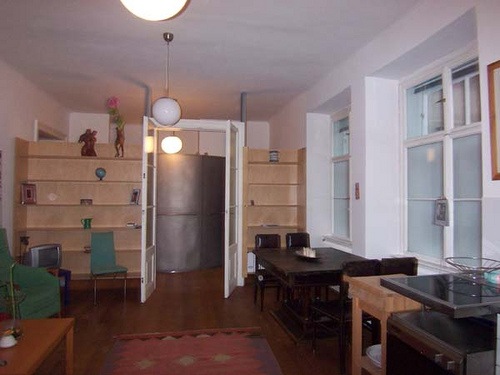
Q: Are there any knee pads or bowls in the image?
A: No, there are no bowls or knee pads.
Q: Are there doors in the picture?
A: Yes, there is a door.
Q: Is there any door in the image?
A: Yes, there is a door.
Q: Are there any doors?
A: Yes, there is a door.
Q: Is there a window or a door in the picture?
A: Yes, there is a door.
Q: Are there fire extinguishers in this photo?
A: No, there are no fire extinguishers.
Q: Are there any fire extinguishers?
A: No, there are no fire extinguishers.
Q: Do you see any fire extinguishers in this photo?
A: No, there are no fire extinguishers.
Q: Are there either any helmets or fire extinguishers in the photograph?
A: No, there are no fire extinguishers or helmets.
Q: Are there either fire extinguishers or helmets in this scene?
A: No, there are no fire extinguishers or helmets.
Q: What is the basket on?
A: The basket is on the counter.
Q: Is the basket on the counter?
A: Yes, the basket is on the counter.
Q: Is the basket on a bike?
A: No, the basket is on the counter.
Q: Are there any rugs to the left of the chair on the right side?
A: Yes, there is a rug to the left of the chair.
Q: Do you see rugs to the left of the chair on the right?
A: Yes, there is a rug to the left of the chair.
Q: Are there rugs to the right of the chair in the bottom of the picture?
A: No, the rug is to the left of the chair.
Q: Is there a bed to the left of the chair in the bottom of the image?
A: No, there is a rug to the left of the chair.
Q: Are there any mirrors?
A: No, there are no mirrors.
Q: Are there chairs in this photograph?
A: Yes, there is a chair.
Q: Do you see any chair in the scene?
A: Yes, there is a chair.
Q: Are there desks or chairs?
A: Yes, there is a chair.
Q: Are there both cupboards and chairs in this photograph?
A: No, there is a chair but no cupboards.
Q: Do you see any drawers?
A: No, there are no drawers.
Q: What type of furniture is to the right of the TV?
A: The piece of furniture is a chair.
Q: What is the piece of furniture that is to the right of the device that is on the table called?
A: The piece of furniture is a chair.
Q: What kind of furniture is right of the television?
A: The piece of furniture is a chair.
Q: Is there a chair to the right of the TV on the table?
A: Yes, there is a chair to the right of the TV.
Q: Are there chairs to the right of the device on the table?
A: Yes, there is a chair to the right of the TV.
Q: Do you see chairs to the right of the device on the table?
A: Yes, there is a chair to the right of the TV.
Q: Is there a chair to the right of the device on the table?
A: Yes, there is a chair to the right of the TV.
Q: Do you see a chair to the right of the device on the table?
A: Yes, there is a chair to the right of the TV.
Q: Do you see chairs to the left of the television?
A: No, the chair is to the right of the television.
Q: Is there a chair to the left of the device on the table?
A: No, the chair is to the right of the television.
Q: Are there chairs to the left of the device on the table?
A: No, the chair is to the right of the television.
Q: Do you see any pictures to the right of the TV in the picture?
A: No, there is a chair to the right of the TV.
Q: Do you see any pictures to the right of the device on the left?
A: No, there is a chair to the right of the TV.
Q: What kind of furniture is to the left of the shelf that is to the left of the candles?
A: The piece of furniture is a chair.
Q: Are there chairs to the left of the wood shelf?
A: Yes, there is a chair to the left of the shelf.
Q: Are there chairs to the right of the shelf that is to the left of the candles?
A: No, the chair is to the left of the shelf.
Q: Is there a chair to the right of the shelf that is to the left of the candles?
A: No, the chair is to the left of the shelf.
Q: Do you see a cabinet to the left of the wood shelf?
A: No, there is a chair to the left of the shelf.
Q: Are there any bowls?
A: No, there are no bowls.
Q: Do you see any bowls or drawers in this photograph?
A: No, there are no bowls or drawers.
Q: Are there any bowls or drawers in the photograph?
A: No, there are no bowls or drawers.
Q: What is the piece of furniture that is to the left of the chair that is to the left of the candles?
A: The piece of furniture is a shelf.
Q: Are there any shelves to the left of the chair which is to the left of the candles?
A: Yes, there is a shelf to the left of the chair.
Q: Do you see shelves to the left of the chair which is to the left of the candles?
A: Yes, there is a shelf to the left of the chair.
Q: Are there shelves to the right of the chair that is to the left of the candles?
A: No, the shelf is to the left of the chair.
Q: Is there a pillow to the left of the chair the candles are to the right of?
A: No, there is a shelf to the left of the chair.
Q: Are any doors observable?
A: Yes, there are doors.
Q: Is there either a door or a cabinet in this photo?
A: Yes, there are doors.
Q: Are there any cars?
A: No, there are no cars.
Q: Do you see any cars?
A: No, there are no cars.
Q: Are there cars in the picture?
A: No, there are no cars.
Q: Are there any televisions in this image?
A: Yes, there is a television.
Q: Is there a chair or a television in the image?
A: Yes, there is a television.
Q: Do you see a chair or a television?
A: Yes, there is a television.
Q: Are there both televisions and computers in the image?
A: No, there is a television but no computers.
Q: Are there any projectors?
A: No, there are no projectors.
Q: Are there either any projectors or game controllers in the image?
A: No, there are no projectors or game controllers.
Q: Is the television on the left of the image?
A: Yes, the television is on the left of the image.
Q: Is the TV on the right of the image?
A: No, the TV is on the left of the image.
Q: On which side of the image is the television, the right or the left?
A: The television is on the left of the image.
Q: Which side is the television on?
A: The television is on the left of the image.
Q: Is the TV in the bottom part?
A: Yes, the TV is in the bottom of the image.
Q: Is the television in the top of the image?
A: No, the television is in the bottom of the image.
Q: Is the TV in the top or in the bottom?
A: The TV is in the bottom of the image.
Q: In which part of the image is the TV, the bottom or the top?
A: The TV is in the bottom of the image.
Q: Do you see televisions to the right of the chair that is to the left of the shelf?
A: No, the television is to the left of the chair.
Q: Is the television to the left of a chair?
A: Yes, the television is to the left of a chair.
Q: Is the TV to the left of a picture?
A: No, the TV is to the left of a chair.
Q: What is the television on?
A: The television is on the table.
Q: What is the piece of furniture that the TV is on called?
A: The piece of furniture is a table.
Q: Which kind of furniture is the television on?
A: The TV is on the table.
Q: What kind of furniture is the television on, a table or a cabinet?
A: The television is on a table.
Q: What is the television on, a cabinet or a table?
A: The television is on a table.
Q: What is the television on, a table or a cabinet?
A: The television is on a table.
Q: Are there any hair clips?
A: No, there are no hair clips.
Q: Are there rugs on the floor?
A: Yes, there is a rug on the floor.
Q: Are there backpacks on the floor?
A: No, there is a rug on the floor.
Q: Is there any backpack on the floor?
A: No, there is a rug on the floor.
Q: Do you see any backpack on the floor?
A: No, there is a rug on the floor.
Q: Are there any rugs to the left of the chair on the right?
A: Yes, there is a rug to the left of the chair.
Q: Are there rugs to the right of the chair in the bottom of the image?
A: No, the rug is to the left of the chair.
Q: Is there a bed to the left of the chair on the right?
A: No, there is a rug to the left of the chair.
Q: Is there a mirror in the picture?
A: No, there are no mirrors.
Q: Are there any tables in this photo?
A: Yes, there is a table.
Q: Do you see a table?
A: Yes, there is a table.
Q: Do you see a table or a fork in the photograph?
A: Yes, there is a table.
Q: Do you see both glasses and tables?
A: No, there is a table but no glasses.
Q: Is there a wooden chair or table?
A: Yes, there is a wood table.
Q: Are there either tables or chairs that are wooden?
A: Yes, the table is wooden.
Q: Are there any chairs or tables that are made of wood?
A: Yes, the table is made of wood.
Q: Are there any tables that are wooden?
A: Yes, there is a wood table.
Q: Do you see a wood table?
A: Yes, there is a table that is made of wood.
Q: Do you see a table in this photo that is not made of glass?
A: Yes, there is a table that is made of wood.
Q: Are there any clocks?
A: No, there are no clocks.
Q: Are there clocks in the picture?
A: No, there are no clocks.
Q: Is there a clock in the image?
A: No, there are no clocks.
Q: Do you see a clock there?
A: No, there are no clocks.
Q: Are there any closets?
A: No, there are no closets.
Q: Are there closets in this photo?
A: No, there are no closets.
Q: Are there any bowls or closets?
A: No, there are no closets or bowls.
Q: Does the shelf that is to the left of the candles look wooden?
A: Yes, the shelf is wooden.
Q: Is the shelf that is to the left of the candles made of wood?
A: Yes, the shelf is made of wood.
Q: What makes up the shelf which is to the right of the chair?
A: The shelf is made of wood.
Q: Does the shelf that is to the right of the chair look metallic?
A: No, the shelf is wooden.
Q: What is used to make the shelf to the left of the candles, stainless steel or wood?
A: The shelf is made of wood.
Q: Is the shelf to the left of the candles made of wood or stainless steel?
A: The shelf is made of wood.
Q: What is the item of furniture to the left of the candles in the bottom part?
A: The piece of furniture is a shelf.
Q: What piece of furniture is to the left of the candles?
A: The piece of furniture is a shelf.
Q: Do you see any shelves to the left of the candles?
A: Yes, there is a shelf to the left of the candles.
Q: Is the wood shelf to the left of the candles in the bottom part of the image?
A: Yes, the shelf is to the left of the candles.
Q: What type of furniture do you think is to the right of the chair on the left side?
A: The piece of furniture is a shelf.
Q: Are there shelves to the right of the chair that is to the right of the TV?
A: Yes, there is a shelf to the right of the chair.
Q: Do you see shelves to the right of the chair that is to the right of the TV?
A: Yes, there is a shelf to the right of the chair.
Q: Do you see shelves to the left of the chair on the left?
A: No, the shelf is to the right of the chair.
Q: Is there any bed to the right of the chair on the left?
A: No, there is a shelf to the right of the chair.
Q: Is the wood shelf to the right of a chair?
A: Yes, the shelf is to the right of a chair.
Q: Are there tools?
A: No, there are no tools.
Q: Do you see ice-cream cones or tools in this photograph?
A: No, there are no tools or ice-cream cones.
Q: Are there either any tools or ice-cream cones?
A: No, there are no tools or ice-cream cones.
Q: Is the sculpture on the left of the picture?
A: Yes, the sculpture is on the left of the image.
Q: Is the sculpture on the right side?
A: No, the sculpture is on the left of the image.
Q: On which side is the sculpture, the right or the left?
A: The sculpture is on the left of the image.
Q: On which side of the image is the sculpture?
A: The sculpture is on the left of the image.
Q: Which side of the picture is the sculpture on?
A: The sculpture is on the left of the image.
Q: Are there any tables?
A: Yes, there is a table.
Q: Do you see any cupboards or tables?
A: Yes, there is a table.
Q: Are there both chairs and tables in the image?
A: Yes, there are both a table and a chair.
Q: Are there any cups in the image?
A: No, there are no cups.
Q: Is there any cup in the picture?
A: No, there are no cups.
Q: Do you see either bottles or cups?
A: No, there are no cups or bottles.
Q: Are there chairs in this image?
A: Yes, there is a chair.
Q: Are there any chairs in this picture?
A: Yes, there is a chair.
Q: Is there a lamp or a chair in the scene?
A: Yes, there is a chair.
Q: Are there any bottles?
A: No, there are no bottles.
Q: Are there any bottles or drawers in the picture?
A: No, there are no bottles or drawers.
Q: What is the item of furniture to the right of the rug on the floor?
A: The piece of furniture is a chair.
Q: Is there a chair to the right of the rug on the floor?
A: Yes, there is a chair to the right of the rug.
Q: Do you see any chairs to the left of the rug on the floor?
A: No, the chair is to the right of the rug.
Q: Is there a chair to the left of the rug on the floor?
A: No, the chair is to the right of the rug.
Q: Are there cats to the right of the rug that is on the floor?
A: No, there is a chair to the right of the rug.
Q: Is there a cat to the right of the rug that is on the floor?
A: No, there is a chair to the right of the rug.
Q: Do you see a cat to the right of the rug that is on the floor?
A: No, there is a chair to the right of the rug.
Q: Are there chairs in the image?
A: Yes, there is a chair.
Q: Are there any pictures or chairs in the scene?
A: Yes, there is a chair.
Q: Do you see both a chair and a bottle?
A: No, there is a chair but no bottles.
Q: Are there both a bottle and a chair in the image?
A: No, there is a chair but no bottles.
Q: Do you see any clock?
A: No, there are no clocks.